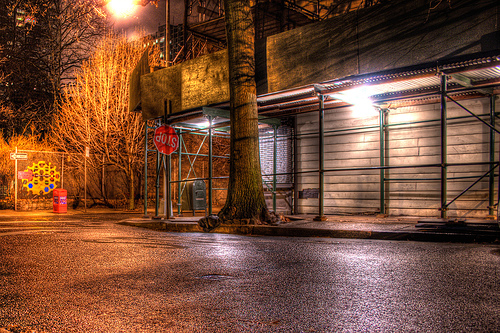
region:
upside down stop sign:
[149, 117, 182, 157]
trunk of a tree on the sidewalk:
[221, 2, 277, 226]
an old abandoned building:
[149, 11, 499, 248]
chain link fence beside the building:
[11, 146, 153, 205]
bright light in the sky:
[101, 0, 146, 25]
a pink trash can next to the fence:
[51, 185, 68, 217]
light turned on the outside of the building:
[331, 83, 386, 123]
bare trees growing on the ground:
[50, 36, 162, 212]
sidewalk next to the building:
[139, 214, 499, 241]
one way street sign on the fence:
[8, 152, 30, 160]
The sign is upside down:
[142, 118, 188, 165]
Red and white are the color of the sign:
[141, 124, 193, 166]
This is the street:
[53, 235, 267, 325]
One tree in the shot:
[173, 5, 310, 240]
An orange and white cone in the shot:
[44, 180, 75, 219]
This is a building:
[116, 28, 498, 268]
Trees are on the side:
[41, 30, 277, 232]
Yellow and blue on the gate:
[11, 147, 72, 213]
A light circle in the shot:
[88, 1, 165, 34]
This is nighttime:
[72, 6, 163, 58]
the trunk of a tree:
[224, 11, 264, 225]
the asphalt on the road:
[26, 224, 373, 330]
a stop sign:
[155, 123, 184, 159]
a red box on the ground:
[50, 184, 66, 204]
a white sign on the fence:
[9, 152, 28, 157]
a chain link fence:
[14, 153, 241, 209]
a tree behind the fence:
[56, 40, 159, 158]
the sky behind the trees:
[88, 11, 148, 31]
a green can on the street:
[181, 175, 203, 205]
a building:
[176, 15, 498, 225]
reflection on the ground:
[292, 231, 394, 309]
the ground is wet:
[45, 233, 123, 318]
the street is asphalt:
[255, 252, 391, 324]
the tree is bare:
[32, 81, 147, 157]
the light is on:
[332, 70, 389, 107]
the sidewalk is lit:
[303, 206, 401, 239]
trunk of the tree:
[180, 175, 297, 222]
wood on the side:
[135, 58, 225, 99]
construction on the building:
[334, 33, 472, 221]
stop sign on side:
[151, 113, 186, 167]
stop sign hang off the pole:
[140, 118, 188, 165]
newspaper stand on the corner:
[49, 183, 76, 215]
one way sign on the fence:
[10, 148, 29, 162]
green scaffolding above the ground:
[133, 7, 440, 122]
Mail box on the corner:
[179, 173, 206, 211]